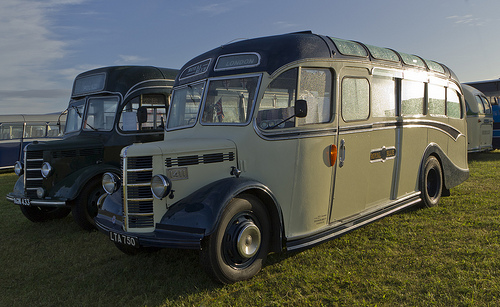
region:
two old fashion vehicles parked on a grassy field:
[4, 27, 471, 282]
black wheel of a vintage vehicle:
[207, 193, 283, 281]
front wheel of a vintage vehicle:
[209, 192, 274, 279]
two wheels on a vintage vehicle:
[202, 155, 462, 283]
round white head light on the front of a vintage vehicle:
[147, 172, 169, 198]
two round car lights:
[100, 166, 175, 198]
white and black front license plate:
[104, 230, 139, 245]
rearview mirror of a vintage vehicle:
[263, 97, 309, 124]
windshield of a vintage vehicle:
[160, 68, 267, 131]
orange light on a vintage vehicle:
[324, 142, 339, 167]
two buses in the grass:
[25, 12, 488, 276]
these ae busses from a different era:
[32, 30, 484, 273]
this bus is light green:
[146, 56, 498, 253]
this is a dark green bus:
[5, 65, 164, 225]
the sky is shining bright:
[8, 6, 498, 89]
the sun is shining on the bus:
[167, 41, 485, 292]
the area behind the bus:
[5, 96, 68, 139]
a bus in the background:
[455, 62, 495, 167]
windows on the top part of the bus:
[43, 42, 279, 102]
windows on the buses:
[123, 71, 482, 128]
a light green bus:
[90, 31, 468, 279]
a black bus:
[8, 62, 184, 229]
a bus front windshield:
[205, 78, 258, 125]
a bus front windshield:
[167, 81, 204, 130]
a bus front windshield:
[83, 95, 118, 133]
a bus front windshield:
[61, 99, 83, 135]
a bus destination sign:
[215, 52, 259, 69]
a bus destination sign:
[180, 54, 210, 78]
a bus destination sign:
[71, 70, 105, 95]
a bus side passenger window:
[340, 75, 367, 120]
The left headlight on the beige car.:
[96, 175, 119, 189]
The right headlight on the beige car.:
[147, 163, 175, 203]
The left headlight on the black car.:
[12, 155, 29, 187]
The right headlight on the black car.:
[34, 159, 54, 176]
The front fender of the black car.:
[4, 182, 63, 212]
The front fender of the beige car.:
[90, 209, 205, 260]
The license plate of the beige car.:
[108, 223, 140, 249]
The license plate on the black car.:
[11, 194, 28, 205]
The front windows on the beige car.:
[170, 81, 261, 130]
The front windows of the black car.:
[69, 96, 126, 124]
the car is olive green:
[95, 29, 465, 280]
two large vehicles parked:
[6, 32, 466, 273]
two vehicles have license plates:
[12, 198, 141, 246]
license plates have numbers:
[12, 196, 139, 246]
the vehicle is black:
[8, 65, 184, 227]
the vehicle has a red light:
[326, 143, 337, 165]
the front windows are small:
[169, 74, 261, 131]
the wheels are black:
[206, 154, 442, 289]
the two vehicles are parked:
[10, 33, 468, 278]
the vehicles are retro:
[12, 34, 468, 271]